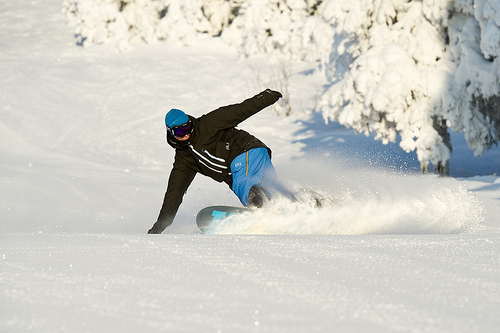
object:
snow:
[309, 180, 409, 267]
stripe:
[245, 150, 249, 175]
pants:
[230, 145, 298, 209]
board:
[196, 205, 255, 234]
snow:
[33, 223, 225, 330]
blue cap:
[165, 108, 190, 128]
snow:
[207, 146, 482, 240]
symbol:
[235, 161, 242, 167]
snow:
[51, 96, 102, 163]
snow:
[365, 205, 456, 228]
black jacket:
[147, 89, 283, 235]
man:
[147, 88, 289, 233]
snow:
[2, 0, 498, 330]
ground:
[1, 1, 493, 331]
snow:
[399, 125, 429, 161]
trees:
[316, 20, 479, 180]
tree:
[307, 2, 494, 168]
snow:
[384, 57, 457, 111]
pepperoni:
[306, 238, 461, 320]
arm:
[152, 159, 201, 229]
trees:
[269, 24, 493, 136]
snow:
[202, 215, 342, 280]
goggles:
[169, 121, 193, 138]